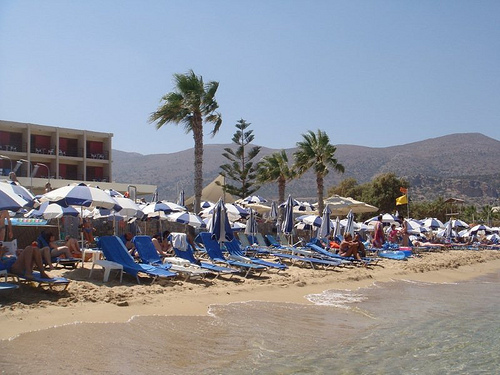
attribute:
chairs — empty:
[101, 216, 363, 296]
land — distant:
[109, 133, 497, 202]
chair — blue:
[132, 233, 216, 280]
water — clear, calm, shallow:
[105, 336, 479, 373]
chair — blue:
[88, 227, 174, 285]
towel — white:
[169, 229, 193, 255]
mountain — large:
[303, 133, 498, 171]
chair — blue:
[224, 238, 287, 275]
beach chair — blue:
[97, 234, 177, 281]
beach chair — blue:
[135, 235, 212, 278]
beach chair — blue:
[170, 230, 239, 276]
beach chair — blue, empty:
[197, 232, 266, 278]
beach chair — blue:
[223, 238, 288, 271]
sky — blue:
[1, 3, 498, 157]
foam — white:
[1, 275, 499, 345]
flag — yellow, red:
[395, 183, 412, 221]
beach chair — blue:
[275, 249, 337, 266]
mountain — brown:
[108, 132, 498, 206]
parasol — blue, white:
[31, 176, 123, 232]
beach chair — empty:
[97, 230, 164, 285]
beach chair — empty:
[132, 236, 164, 266]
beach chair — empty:
[167, 232, 232, 283]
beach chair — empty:
[223, 239, 288, 279]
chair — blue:
[198, 228, 266, 271]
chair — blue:
[26, 229, 86, 269]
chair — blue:
[98, 232, 179, 279]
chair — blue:
[166, 227, 234, 277]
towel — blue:
[95, 232, 162, 274]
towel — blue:
[135, 234, 185, 268]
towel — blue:
[171, 246, 221, 271]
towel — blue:
[197, 229, 226, 262]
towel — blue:
[220, 238, 248, 256]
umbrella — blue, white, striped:
[0, 178, 39, 215]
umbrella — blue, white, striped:
[43, 179, 121, 214]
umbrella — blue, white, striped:
[145, 199, 185, 213]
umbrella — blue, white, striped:
[164, 208, 206, 230]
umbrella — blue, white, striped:
[421, 218, 443, 227]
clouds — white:
[10, 14, 131, 103]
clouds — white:
[379, 47, 439, 96]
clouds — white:
[319, 22, 440, 105]